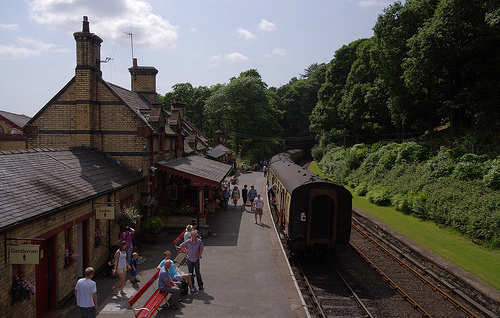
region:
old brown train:
[284, 159, 337, 252]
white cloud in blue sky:
[11, 4, 66, 50]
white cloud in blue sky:
[4, 37, 50, 73]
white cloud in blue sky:
[105, 9, 163, 33]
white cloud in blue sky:
[132, 6, 203, 42]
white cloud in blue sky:
[168, 7, 248, 61]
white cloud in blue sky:
[257, 0, 328, 51]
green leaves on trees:
[376, 48, 464, 120]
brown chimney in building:
[39, 19, 133, 134]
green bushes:
[355, 155, 422, 186]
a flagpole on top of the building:
[121, 30, 138, 86]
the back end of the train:
[283, 180, 352, 254]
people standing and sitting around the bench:
[72, 221, 202, 314]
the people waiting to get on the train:
[228, 181, 268, 225]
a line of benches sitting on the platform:
[127, 225, 198, 312]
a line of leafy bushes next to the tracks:
[314, 145, 495, 249]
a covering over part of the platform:
[160, 156, 232, 198]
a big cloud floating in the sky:
[56, 0, 165, 45]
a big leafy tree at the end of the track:
[204, 60, 280, 165]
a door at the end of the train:
[304, 189, 336, 249]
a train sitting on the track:
[267, 145, 358, 255]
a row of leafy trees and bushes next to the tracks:
[258, 1, 496, 247]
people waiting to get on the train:
[231, 178, 267, 228]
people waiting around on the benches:
[151, 225, 216, 313]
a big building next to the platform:
[35, 28, 237, 249]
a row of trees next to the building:
[123, 222, 208, 316]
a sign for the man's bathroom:
[1, 235, 45, 267]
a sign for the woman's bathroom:
[93, 200, 118, 223]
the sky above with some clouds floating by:
[8, 4, 365, 76]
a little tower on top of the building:
[66, 18, 104, 77]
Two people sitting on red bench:
[126, 248, 200, 316]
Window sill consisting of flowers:
[8, 250, 37, 305]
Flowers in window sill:
[7, 245, 37, 306]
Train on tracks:
[268, 144, 499, 316]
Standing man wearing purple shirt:
[178, 229, 205, 291]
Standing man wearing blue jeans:
[178, 229, 205, 291]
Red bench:
[127, 265, 177, 316]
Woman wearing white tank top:
[112, 239, 129, 295]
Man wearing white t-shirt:
[73, 267, 100, 317]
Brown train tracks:
[349, 222, 476, 317]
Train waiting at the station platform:
[263, 152, 349, 248]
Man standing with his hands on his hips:
[180, 232, 207, 294]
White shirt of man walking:
[73, 277, 98, 310]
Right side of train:
[263, 162, 293, 234]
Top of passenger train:
[268, 158, 353, 193]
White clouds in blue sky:
[0, 1, 402, 119]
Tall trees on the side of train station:
[163, 0, 496, 252]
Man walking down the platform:
[251, 192, 266, 227]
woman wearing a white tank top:
[112, 242, 129, 279]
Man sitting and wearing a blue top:
[158, 250, 203, 300]